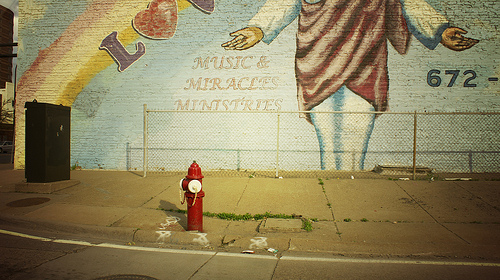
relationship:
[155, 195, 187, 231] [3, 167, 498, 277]
shadow on pavement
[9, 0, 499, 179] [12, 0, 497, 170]
mural on building exterior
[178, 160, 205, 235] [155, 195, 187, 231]
hydrant casting shadow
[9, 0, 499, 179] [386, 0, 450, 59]
mural portrays arm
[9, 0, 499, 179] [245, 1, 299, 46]
mural portrays arm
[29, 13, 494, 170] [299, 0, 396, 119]
mural portrays robe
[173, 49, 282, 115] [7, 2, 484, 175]
lettering on wall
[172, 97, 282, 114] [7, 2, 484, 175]
lettering on wall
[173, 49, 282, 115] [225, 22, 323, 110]
lettering on wall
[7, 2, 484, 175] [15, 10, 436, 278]
wall on side of a building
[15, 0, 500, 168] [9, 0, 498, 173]
painting on building